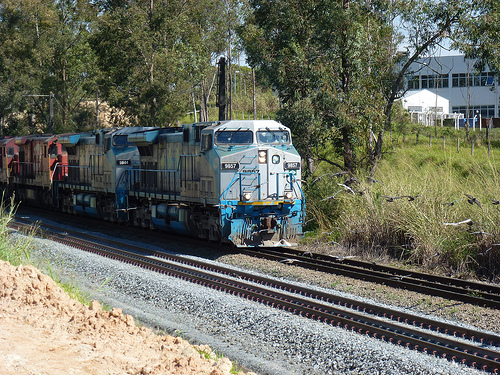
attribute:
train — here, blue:
[1, 119, 305, 251]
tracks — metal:
[243, 248, 499, 308]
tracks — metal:
[1, 215, 499, 375]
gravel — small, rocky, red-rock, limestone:
[7, 227, 500, 375]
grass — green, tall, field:
[302, 123, 498, 282]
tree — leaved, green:
[237, 0, 500, 194]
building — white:
[392, 37, 499, 128]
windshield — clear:
[213, 129, 254, 145]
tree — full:
[450, 0, 500, 91]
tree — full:
[88, 0, 254, 127]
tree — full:
[1, 1, 60, 130]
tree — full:
[49, 29, 95, 131]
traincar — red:
[8, 133, 67, 211]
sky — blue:
[390, 1, 482, 56]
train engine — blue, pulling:
[129, 121, 305, 247]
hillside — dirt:
[2, 261, 255, 374]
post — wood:
[469, 139, 474, 157]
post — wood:
[456, 137, 461, 154]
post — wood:
[485, 126, 491, 144]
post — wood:
[441, 138, 447, 150]